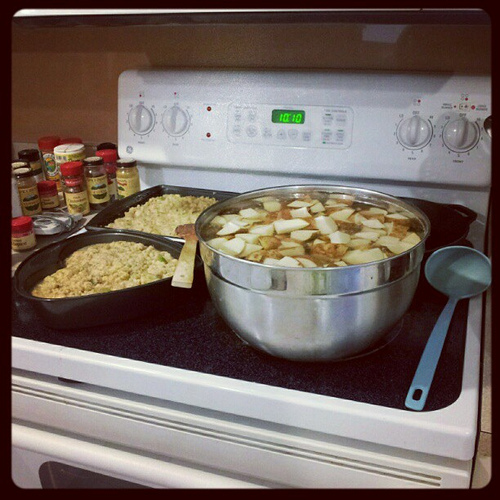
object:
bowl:
[194, 184, 432, 367]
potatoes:
[313, 215, 339, 236]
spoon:
[404, 245, 492, 410]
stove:
[7, 187, 481, 416]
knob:
[125, 103, 155, 136]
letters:
[275, 111, 302, 124]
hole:
[411, 388, 423, 400]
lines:
[3, 373, 469, 500]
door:
[8, 382, 445, 492]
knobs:
[123, 103, 190, 137]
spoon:
[171, 225, 197, 289]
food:
[105, 192, 221, 238]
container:
[61, 162, 90, 217]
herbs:
[65, 184, 85, 193]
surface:
[3, 275, 465, 412]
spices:
[115, 168, 141, 199]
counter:
[0, 141, 140, 361]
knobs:
[394, 111, 433, 150]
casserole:
[10, 228, 205, 332]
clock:
[271, 108, 306, 125]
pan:
[85, 183, 237, 247]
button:
[325, 113, 332, 116]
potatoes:
[272, 216, 310, 236]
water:
[201, 187, 420, 268]